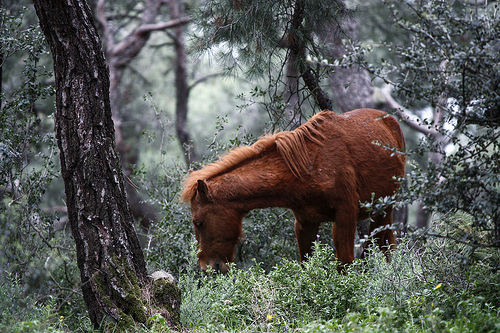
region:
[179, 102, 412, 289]
reddish brown horse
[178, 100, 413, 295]
horse grazing on plants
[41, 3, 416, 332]
horse eating by tree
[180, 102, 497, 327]
horse by over grown vegetation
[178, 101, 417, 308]
horse eating ground vegetation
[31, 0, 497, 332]
ground cover near tree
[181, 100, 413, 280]
horse with messy mane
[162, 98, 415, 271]
horse with matted coat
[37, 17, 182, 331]
tree with moss on bark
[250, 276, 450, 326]
yellow flowers in vegetataion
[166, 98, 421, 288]
horse photoshopped a hard rust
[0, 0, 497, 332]
background desaturated to feature hard rust of horse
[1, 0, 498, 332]
this picture & the last one are someone's class assignments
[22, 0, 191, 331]
trunk of tree force-focussed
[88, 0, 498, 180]
background hit with some kind of blur filter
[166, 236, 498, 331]
grasses+weeds in foreground maybe left alone other than desaturation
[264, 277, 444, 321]
two yellow dandelions in the foreground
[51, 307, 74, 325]
one tiny yellow dandelion in the corner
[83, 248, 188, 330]
moss on bottom of tree trunk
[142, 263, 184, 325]
weird little part of tree that looks like a gargoyle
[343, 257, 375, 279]
part of a plant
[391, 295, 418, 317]
part of a plant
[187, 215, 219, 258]
part of a horse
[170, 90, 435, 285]
the horse is redish brown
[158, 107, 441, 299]
the horse is eating the vegetation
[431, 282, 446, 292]
a yellow flower among the plants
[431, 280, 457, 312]
the flower is a dandy lion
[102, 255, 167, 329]
a patch of moss on the tree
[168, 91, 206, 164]
a tree out of focus in the background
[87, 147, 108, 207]
the bark of the tree is dark brown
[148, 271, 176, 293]
a stone besides the tree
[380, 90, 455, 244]
this tree looks like its color is white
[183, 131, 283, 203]
the mane on the horse is light red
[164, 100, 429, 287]
horse in the grass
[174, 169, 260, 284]
head bent down towards the ground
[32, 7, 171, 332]
dark brown bark on the tree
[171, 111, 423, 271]
brown horse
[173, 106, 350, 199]
hair running along the neck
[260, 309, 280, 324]
small yellow flower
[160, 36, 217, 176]
skinny tree trunk in the background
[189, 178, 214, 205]
ear sticking up off the head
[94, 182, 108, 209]
white spot on tree trunk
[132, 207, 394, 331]
tall green grass